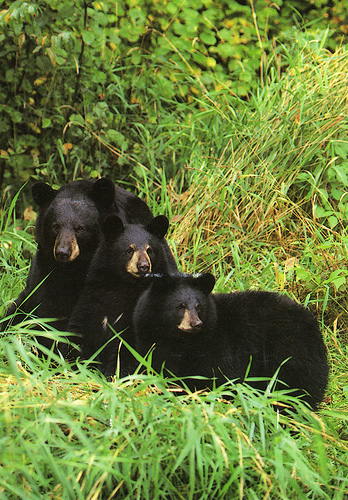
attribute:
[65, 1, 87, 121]
stem — brown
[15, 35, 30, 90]
stem — brown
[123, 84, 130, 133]
stem — brown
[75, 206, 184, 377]
bear — black, fury, sitted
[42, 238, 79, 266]
nose — long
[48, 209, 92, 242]
eye — open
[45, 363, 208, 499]
grass — tall, green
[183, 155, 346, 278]
foilage — green